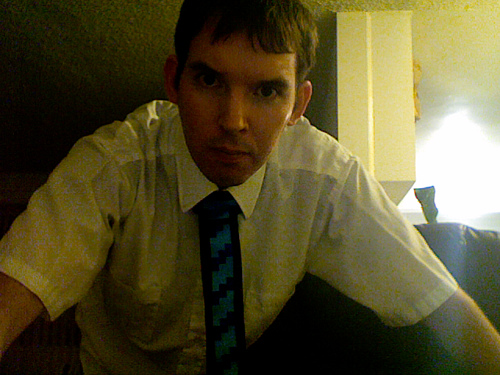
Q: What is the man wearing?
A: A black tie.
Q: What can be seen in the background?
A: A white box.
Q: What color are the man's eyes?
A: Brown.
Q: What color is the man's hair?
A: Brown.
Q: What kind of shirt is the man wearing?
A: Short sleeve button up.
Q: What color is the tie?
A: Blue.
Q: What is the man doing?
A: Leaning over.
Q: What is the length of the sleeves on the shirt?
A: Short.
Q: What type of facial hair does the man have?
A: None.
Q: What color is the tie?
A: Black and blue.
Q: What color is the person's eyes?
A: Brown.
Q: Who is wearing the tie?
A: A man.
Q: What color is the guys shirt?
A: White.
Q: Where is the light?
A: To the right.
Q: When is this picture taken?
A: Evening.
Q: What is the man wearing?
A: A shirt.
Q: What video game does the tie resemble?
A: Tetris.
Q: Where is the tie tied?
A: Around the collar.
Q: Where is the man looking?
A: Forward.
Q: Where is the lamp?
A: Behind the man.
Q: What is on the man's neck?
A: A tie.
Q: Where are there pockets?
A: On the shirt.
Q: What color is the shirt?
A: White.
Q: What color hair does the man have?
A: Brown.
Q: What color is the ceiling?
A: White.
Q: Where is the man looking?
A: Forward.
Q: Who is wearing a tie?
A: The man.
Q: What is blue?
A: Tie.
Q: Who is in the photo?
A: A man.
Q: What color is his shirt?
A: White.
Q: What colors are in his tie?
A: Black and blue.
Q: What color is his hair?
A: Brown.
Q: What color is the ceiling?
A: White.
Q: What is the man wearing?
A: A white dress shirt and a tie.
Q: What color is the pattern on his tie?
A: Blue.